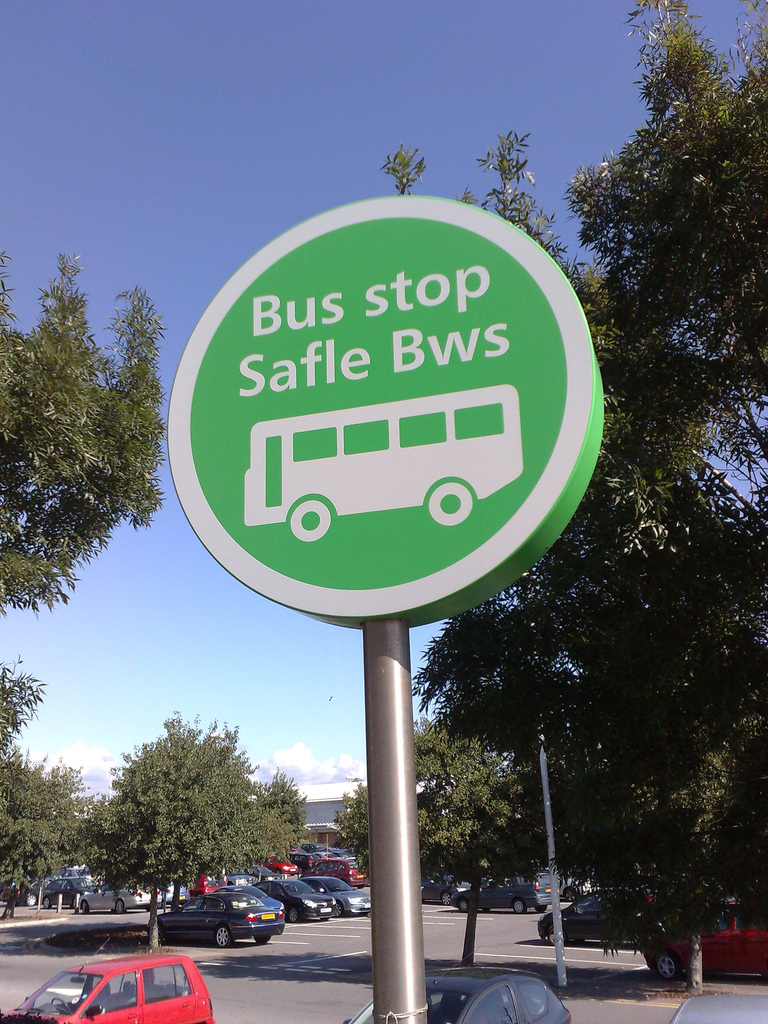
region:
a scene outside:
[7, 6, 765, 1019]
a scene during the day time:
[3, 16, 762, 1019]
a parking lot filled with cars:
[10, 698, 763, 1018]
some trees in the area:
[6, 141, 764, 967]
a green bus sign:
[135, 164, 630, 1021]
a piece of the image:
[127, 827, 134, 873]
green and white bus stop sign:
[184, 157, 600, 666]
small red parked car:
[13, 948, 213, 1022]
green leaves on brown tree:
[13, 393, 68, 454]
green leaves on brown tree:
[43, 413, 96, 475]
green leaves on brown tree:
[598, 682, 664, 752]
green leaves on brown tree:
[641, 603, 701, 678]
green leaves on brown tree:
[624, 229, 658, 279]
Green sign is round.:
[182, 247, 593, 610]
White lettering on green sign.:
[228, 284, 522, 387]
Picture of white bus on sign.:
[232, 404, 527, 542]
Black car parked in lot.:
[391, 934, 553, 1018]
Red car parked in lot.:
[23, 959, 232, 1019]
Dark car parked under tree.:
[165, 885, 279, 942]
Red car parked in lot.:
[661, 868, 765, 996]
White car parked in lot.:
[83, 874, 160, 912]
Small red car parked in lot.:
[316, 849, 377, 887]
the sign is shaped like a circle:
[165, 194, 604, 628]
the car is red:
[4, 953, 217, 1022]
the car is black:
[339, 962, 568, 1022]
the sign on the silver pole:
[167, 195, 603, 1021]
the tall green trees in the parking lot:
[2, 0, 766, 1020]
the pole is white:
[533, 717, 567, 986]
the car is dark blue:
[157, 888, 283, 945]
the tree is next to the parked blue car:
[66, 706, 283, 949]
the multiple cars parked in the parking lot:
[0, 839, 766, 1021]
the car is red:
[646, 894, 765, 981]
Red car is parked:
[0, 936, 245, 1020]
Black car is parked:
[340, 952, 593, 1022]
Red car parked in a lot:
[0, 943, 222, 1019]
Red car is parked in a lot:
[0, 942, 219, 1019]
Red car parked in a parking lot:
[0, 944, 222, 1020]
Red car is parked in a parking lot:
[0, 930, 233, 1021]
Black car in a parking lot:
[346, 960, 582, 1022]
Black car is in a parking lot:
[332, 940, 584, 1021]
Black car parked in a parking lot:
[335, 953, 582, 1022]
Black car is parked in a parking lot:
[331, 949, 592, 1022]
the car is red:
[0, 950, 215, 1022]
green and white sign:
[162, 193, 606, 620]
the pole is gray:
[358, 623, 433, 1022]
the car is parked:
[147, 884, 286, 947]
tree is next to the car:
[82, 705, 294, 946]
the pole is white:
[536, 735, 566, 986]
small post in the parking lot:
[52, 891, 59, 911]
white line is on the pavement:
[266, 944, 372, 968]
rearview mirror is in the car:
[66, 969, 87, 985]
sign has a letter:
[252, 295, 281, 335]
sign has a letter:
[391, 328, 419, 368]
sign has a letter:
[426, 328, 483, 362]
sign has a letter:
[479, 323, 506, 351]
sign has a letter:
[455, 262, 484, 313]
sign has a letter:
[415, 270, 451, 301]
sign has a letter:
[388, 269, 409, 309]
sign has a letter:
[363, 280, 383, 312]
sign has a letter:
[339, 345, 368, 377]